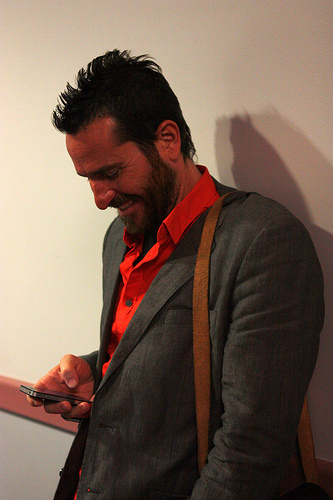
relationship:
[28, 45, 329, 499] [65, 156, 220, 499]
man wearing a shirt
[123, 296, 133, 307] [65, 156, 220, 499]
button on shirt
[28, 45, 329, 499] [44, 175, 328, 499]
man wearing a blazer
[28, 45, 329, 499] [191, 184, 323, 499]
man holding bag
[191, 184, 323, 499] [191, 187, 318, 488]
bag has strap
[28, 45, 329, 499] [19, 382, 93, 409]
man holding mobile phone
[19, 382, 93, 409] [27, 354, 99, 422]
mobile phone in right hand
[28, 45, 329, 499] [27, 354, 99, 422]
man has right hand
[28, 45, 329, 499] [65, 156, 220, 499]
man has shirt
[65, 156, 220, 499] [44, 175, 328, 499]
shirt under blazer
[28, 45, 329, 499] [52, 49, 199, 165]
man has hair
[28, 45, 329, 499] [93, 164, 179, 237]
man has beard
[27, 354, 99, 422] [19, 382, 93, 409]
right hand holding mobile phone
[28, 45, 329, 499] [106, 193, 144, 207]
man has mustache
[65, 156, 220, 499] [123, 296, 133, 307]
shirt has button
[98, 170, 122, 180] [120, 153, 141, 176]
eye has crow's feet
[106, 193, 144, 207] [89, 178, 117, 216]
mustache under a nose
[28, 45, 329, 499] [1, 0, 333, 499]
man leaning against a wall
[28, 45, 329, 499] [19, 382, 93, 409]
man looking at mobile phone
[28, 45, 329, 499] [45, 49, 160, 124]
man has fauxhawk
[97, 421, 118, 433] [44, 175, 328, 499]
button hole on blazer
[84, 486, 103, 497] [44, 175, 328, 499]
button hole on blazer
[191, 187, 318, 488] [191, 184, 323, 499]
strap of a bag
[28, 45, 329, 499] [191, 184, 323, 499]
man has bag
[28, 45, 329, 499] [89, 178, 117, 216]
man has nose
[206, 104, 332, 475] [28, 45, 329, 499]
shadow of a man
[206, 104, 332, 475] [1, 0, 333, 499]
shadow on wall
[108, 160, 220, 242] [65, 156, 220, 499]
collar of shirt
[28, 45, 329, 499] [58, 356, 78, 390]
man has thumb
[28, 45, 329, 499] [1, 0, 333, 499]
man standing against wall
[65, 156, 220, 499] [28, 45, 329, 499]
shirt of man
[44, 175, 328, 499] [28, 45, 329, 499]
blazer of a man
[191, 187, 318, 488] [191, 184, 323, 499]
strap of bag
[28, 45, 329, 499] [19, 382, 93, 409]
man has mobile phone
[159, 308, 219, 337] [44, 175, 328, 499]
pocket on blazer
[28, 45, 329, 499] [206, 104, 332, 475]
man has shadow